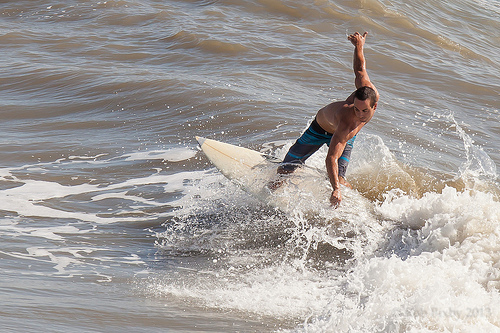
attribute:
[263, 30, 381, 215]
man — white, surfing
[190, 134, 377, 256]
surfboard — white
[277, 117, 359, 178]
shorts — blue, black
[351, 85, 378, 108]
hair — brown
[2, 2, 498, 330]
water — brown, vast, splashing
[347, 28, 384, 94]
arm — sticking up